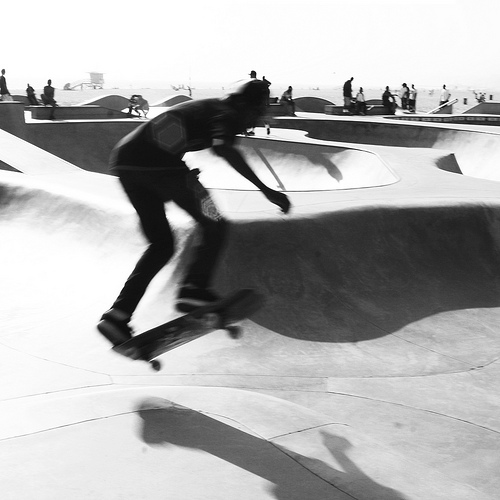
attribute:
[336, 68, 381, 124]
person — here, standing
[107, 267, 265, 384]
skateboard — here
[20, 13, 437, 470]
skatepark — here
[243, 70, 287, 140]
hat — on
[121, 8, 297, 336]
skateboarder — here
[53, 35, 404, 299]
day — here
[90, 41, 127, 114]
tower — here